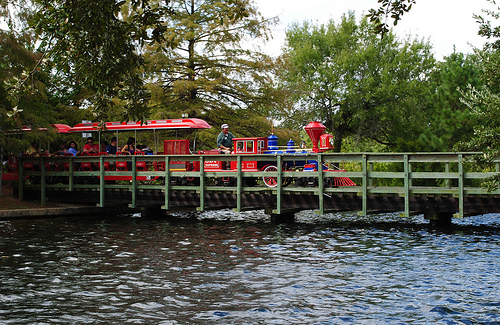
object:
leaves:
[212, 17, 222, 24]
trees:
[270, 9, 437, 179]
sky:
[0, 0, 499, 127]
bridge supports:
[420, 202, 455, 227]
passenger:
[115, 136, 143, 156]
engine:
[196, 122, 316, 189]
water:
[0, 205, 499, 324]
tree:
[98, 0, 302, 147]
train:
[0, 117, 357, 188]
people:
[79, 137, 101, 155]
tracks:
[352, 182, 499, 191]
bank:
[0, 201, 97, 219]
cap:
[218, 123, 230, 130]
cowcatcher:
[298, 119, 357, 188]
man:
[214, 121, 240, 170]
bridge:
[0, 147, 499, 221]